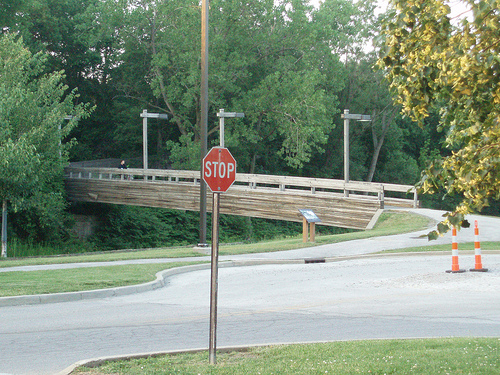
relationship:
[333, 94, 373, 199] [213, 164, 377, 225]
lamp on bridge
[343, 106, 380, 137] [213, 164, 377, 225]
light on bridge